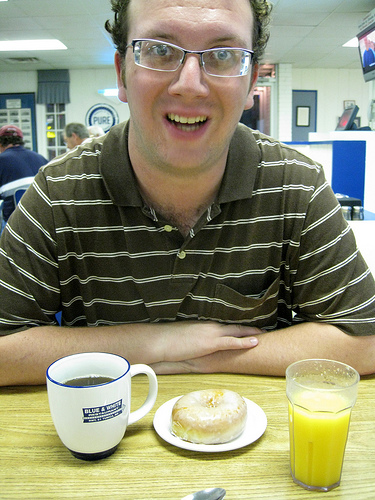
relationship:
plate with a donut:
[153, 390, 269, 452] [169, 386, 247, 444]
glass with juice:
[285, 356, 360, 492] [290, 401, 349, 487]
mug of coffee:
[46, 350, 159, 461] [68, 376, 109, 388]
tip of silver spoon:
[183, 482, 226, 500] [179, 484, 227, 497]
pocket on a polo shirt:
[217, 274, 282, 324] [0, 116, 375, 336]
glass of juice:
[285, 356, 360, 492] [290, 401, 349, 487]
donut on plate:
[169, 386, 247, 444] [153, 390, 269, 452]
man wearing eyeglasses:
[1, 1, 373, 391] [141, 37, 255, 86]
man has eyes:
[1, 1, 373, 391] [138, 43, 230, 59]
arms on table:
[0, 290, 373, 383] [1, 373, 373, 499]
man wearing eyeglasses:
[1, 1, 373, 379] [132, 34, 254, 76]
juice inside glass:
[290, 401, 349, 487] [285, 356, 360, 492]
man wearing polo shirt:
[1, 1, 373, 379] [0, 116, 375, 336]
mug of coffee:
[24, 354, 168, 458] [60, 374, 117, 386]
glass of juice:
[264, 341, 368, 479] [290, 401, 349, 487]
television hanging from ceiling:
[352, 13, 375, 85] [2, 2, 374, 70]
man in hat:
[1, 124, 51, 231] [1, 123, 22, 136]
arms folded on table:
[0, 311, 371, 382] [10, 386, 374, 498]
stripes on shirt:
[48, 186, 114, 262] [46, 146, 322, 314]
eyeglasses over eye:
[126, 38, 258, 78] [147, 40, 175, 62]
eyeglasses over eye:
[126, 38, 258, 78] [208, 44, 235, 62]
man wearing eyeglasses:
[1, 1, 373, 379] [126, 38, 258, 78]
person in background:
[63, 122, 104, 149] [1, 0, 373, 233]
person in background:
[83, 122, 106, 138] [1, 0, 373, 233]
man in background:
[1, 124, 51, 231] [1, 0, 373, 233]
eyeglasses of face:
[126, 38, 258, 78] [117, 0, 258, 171]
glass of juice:
[285, 356, 360, 492] [282, 401, 350, 486]